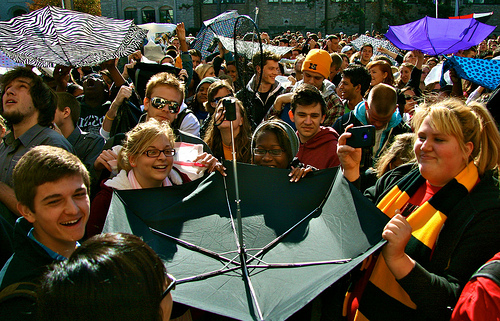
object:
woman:
[362, 99, 500, 317]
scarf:
[358, 164, 483, 321]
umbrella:
[106, 161, 388, 320]